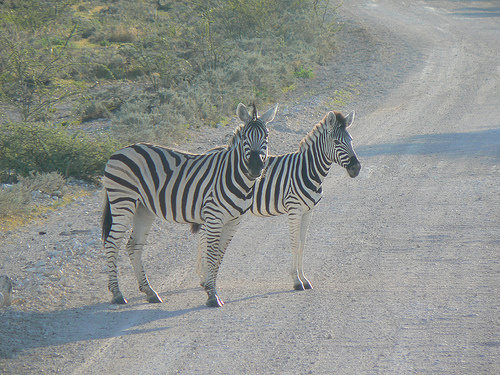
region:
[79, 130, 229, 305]
this is a zebra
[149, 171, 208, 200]
the zebra has white and black strips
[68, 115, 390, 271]
the zebras are two in number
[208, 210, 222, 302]
this is the leg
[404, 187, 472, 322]
this is a road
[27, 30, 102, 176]
this is a tree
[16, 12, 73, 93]
the leaves are green in color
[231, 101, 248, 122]
this is the ear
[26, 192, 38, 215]
this is a grass area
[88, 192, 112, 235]
this is the tail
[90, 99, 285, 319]
This is a zebra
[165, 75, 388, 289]
This is a zebra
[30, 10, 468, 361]
two animals on the road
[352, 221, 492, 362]
hard dirt road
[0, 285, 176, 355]
zebra's shadow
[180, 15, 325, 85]
brush on the side of the road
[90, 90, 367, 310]
two zebras standing side by side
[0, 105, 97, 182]
small green bush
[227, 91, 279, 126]
animal's ears sticking straight out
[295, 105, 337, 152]
animal's mane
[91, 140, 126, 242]
hind quarters and black tail of a zebra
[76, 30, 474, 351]
animals standing on the edge of a dirt road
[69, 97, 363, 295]
two zebras on the road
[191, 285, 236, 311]
the hoofs are black in color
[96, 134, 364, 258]
zebras are black and white striped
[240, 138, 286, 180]
the mouth is black in color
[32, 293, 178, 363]
shadow of the zebras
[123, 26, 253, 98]
the plants are beside the road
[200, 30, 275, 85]
plants are green in color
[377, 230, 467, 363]
floor is rugged and rough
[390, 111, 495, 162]
shadow of the plants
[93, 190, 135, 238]
tail is black in color